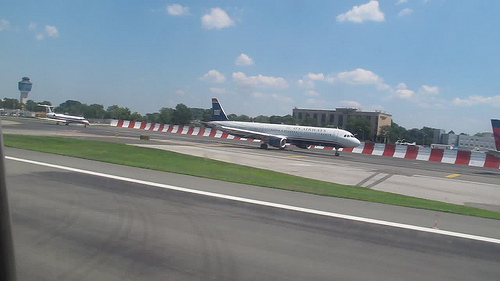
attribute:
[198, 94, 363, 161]
plane — white